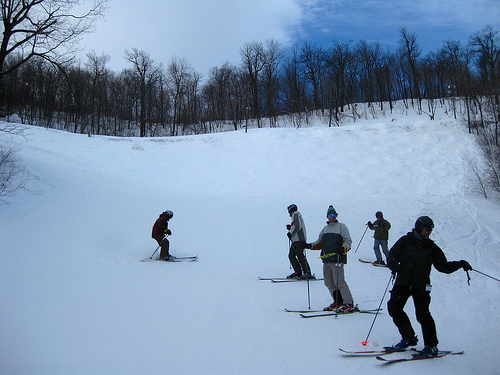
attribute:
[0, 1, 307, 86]
cloud — white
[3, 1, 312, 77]
clouds — white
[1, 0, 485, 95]
sky — blue